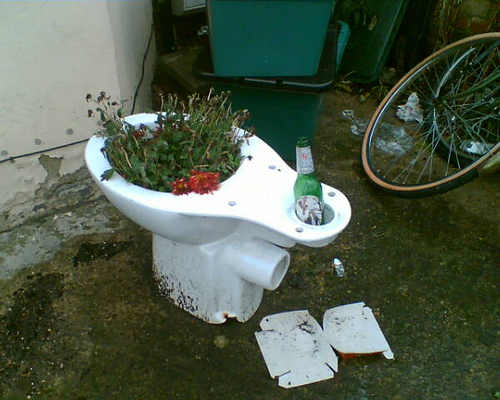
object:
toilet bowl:
[81, 113, 352, 323]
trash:
[255, 301, 397, 391]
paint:
[0, 0, 111, 221]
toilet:
[81, 109, 353, 325]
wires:
[1, 22, 156, 163]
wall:
[1, 0, 157, 236]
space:
[149, 0, 210, 66]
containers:
[207, 0, 338, 80]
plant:
[84, 86, 257, 196]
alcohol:
[293, 136, 326, 226]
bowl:
[103, 120, 244, 193]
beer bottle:
[291, 135, 325, 226]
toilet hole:
[293, 203, 333, 226]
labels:
[295, 195, 323, 226]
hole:
[72, 241, 126, 267]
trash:
[394, 91, 424, 124]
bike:
[358, 32, 500, 200]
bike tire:
[360, 31, 500, 198]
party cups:
[251, 301, 398, 390]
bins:
[192, 0, 352, 165]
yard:
[5, 65, 493, 395]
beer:
[293, 204, 325, 226]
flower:
[98, 90, 108, 100]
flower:
[157, 87, 165, 97]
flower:
[244, 126, 256, 146]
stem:
[104, 117, 136, 170]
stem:
[156, 98, 166, 138]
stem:
[221, 134, 242, 167]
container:
[254, 302, 393, 389]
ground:
[0, 229, 499, 397]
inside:
[273, 320, 318, 369]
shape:
[72, 240, 133, 272]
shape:
[0, 269, 69, 370]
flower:
[188, 147, 195, 155]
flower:
[172, 166, 222, 196]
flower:
[86, 108, 93, 118]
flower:
[131, 130, 143, 140]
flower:
[245, 155, 253, 163]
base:
[0, 194, 132, 326]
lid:
[192, 19, 350, 97]